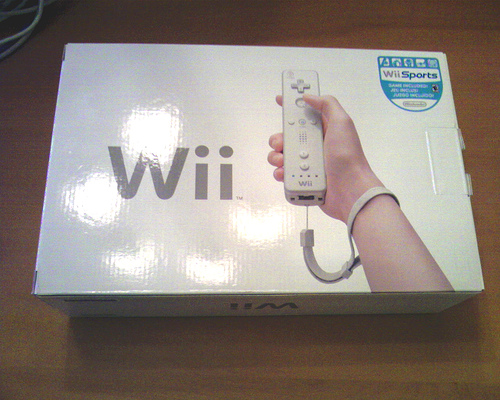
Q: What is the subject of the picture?
A: A box.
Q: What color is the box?
A: White.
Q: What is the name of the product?
A: Wii.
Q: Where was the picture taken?
A: Near a table.